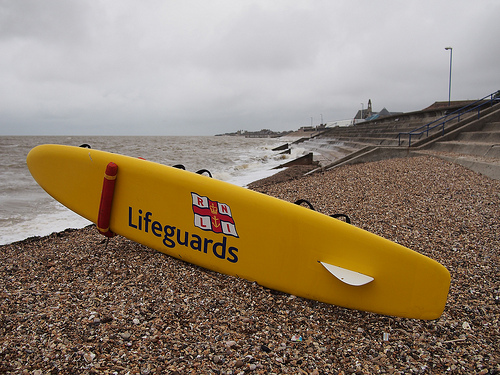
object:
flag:
[190, 189, 240, 241]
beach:
[0, 155, 499, 375]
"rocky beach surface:
[0, 154, 500, 374]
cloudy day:
[0, 0, 499, 138]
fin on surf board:
[316, 261, 379, 289]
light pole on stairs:
[442, 43, 458, 119]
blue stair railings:
[396, 93, 500, 152]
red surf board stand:
[94, 156, 123, 242]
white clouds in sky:
[0, 0, 499, 141]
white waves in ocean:
[210, 140, 314, 192]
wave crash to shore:
[212, 150, 312, 188]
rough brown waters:
[0, 133, 323, 246]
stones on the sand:
[0, 153, 499, 374]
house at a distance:
[349, 101, 399, 126]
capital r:
[191, 192, 209, 210]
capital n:
[217, 200, 233, 216]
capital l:
[194, 213, 211, 229]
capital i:
[218, 221, 240, 241]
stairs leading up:
[281, 98, 499, 204]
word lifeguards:
[122, 203, 245, 270]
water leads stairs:
[274, 133, 343, 169]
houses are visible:
[350, 99, 397, 129]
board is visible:
[24, 141, 453, 325]